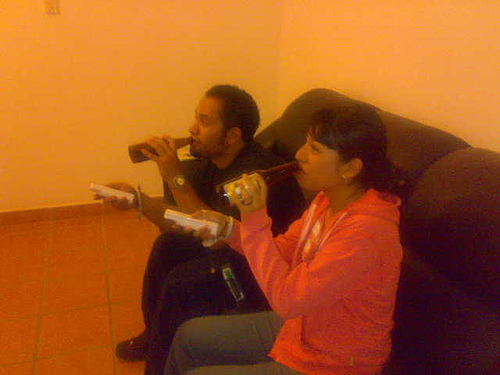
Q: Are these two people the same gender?
A: No, they are both male and female.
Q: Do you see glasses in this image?
A: No, there are no glasses.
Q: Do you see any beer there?
A: Yes, there is beer.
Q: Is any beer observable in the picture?
A: Yes, there is beer.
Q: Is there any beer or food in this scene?
A: Yes, there is beer.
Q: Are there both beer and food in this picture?
A: No, there is beer but no food.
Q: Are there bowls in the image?
A: No, there are no bowls.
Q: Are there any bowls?
A: No, there are no bowls.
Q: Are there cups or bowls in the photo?
A: No, there are no bowls or cups.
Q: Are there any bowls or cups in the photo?
A: No, there are no bowls or cups.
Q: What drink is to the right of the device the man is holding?
A: The drink is beer.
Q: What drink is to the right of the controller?
A: The drink is beer.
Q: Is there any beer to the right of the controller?
A: Yes, there is beer to the right of the controller.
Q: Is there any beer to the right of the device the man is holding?
A: Yes, there is beer to the right of the controller.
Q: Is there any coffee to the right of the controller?
A: No, there is beer to the right of the controller.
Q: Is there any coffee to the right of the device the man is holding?
A: No, there is beer to the right of the controller.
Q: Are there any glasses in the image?
A: No, there are no glasses.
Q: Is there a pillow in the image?
A: No, there are no pillows.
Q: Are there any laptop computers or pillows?
A: No, there are no pillows or laptop computers.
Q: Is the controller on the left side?
A: Yes, the controller is on the left of the image.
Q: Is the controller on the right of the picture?
A: No, the controller is on the left of the image.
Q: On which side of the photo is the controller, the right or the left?
A: The controller is on the left of the image.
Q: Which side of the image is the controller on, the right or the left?
A: The controller is on the left of the image.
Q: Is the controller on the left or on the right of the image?
A: The controller is on the left of the image.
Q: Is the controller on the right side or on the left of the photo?
A: The controller is on the left of the image.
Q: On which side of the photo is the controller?
A: The controller is on the left of the image.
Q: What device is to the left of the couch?
A: The device is a controller.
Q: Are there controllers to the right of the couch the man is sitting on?
A: No, the controller is to the left of the couch.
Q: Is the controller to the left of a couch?
A: Yes, the controller is to the left of a couch.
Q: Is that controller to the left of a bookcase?
A: No, the controller is to the left of a couch.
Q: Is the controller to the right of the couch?
A: No, the controller is to the left of the couch.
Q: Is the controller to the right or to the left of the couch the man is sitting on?
A: The controller is to the left of the couch.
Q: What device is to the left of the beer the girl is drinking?
A: The device is a controller.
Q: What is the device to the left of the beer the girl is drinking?
A: The device is a controller.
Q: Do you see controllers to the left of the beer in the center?
A: Yes, there is a controller to the left of the beer.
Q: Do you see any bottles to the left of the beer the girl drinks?
A: No, there is a controller to the left of the beer.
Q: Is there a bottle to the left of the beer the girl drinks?
A: No, there is a controller to the left of the beer.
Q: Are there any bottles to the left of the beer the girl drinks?
A: No, there is a controller to the left of the beer.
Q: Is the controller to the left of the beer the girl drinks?
A: Yes, the controller is to the left of the beer.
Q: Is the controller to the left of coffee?
A: No, the controller is to the left of the beer.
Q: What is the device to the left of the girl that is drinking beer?
A: The device is a controller.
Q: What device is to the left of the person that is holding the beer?
A: The device is a controller.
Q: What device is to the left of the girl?
A: The device is a controller.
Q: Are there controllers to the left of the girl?
A: Yes, there is a controller to the left of the girl.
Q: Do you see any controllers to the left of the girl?
A: Yes, there is a controller to the left of the girl.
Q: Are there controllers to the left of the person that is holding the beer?
A: Yes, there is a controller to the left of the girl.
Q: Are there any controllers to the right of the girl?
A: No, the controller is to the left of the girl.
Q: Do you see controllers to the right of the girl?
A: No, the controller is to the left of the girl.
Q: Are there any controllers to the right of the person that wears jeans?
A: No, the controller is to the left of the girl.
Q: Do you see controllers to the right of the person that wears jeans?
A: No, the controller is to the left of the girl.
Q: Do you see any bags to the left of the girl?
A: No, there is a controller to the left of the girl.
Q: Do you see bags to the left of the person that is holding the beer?
A: No, there is a controller to the left of the girl.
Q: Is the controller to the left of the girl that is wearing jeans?
A: Yes, the controller is to the left of the girl.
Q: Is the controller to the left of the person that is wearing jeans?
A: Yes, the controller is to the left of the girl.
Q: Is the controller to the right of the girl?
A: No, the controller is to the left of the girl.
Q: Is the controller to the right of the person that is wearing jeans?
A: No, the controller is to the left of the girl.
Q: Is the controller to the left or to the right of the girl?
A: The controller is to the left of the girl.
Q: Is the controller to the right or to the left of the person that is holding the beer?
A: The controller is to the left of the girl.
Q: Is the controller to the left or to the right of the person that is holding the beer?
A: The controller is to the left of the girl.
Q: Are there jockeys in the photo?
A: No, there are no jockeys.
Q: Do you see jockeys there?
A: No, there are no jockeys.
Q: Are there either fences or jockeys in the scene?
A: No, there are no jockeys or fences.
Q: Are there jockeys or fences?
A: No, there are no jockeys or fences.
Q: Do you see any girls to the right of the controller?
A: Yes, there is a girl to the right of the controller.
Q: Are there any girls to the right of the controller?
A: Yes, there is a girl to the right of the controller.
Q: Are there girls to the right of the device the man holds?
A: Yes, there is a girl to the right of the controller.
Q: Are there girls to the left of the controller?
A: No, the girl is to the right of the controller.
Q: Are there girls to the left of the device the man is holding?
A: No, the girl is to the right of the controller.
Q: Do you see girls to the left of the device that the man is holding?
A: No, the girl is to the right of the controller.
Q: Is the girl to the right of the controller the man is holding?
A: Yes, the girl is to the right of the controller.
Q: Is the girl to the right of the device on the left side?
A: Yes, the girl is to the right of the controller.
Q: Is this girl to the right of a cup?
A: No, the girl is to the right of the controller.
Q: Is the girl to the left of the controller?
A: No, the girl is to the right of the controller.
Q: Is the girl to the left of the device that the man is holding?
A: No, the girl is to the right of the controller.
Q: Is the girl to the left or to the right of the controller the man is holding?
A: The girl is to the right of the controller.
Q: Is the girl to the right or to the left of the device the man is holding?
A: The girl is to the right of the controller.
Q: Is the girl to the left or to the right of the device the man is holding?
A: The girl is to the right of the controller.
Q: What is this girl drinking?
A: The girl is drinking beer.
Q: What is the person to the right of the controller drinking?
A: The girl is drinking beer.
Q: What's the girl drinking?
A: The girl is drinking beer.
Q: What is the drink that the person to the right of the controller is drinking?
A: The drink is beer.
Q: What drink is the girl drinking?
A: The girl is drinking beer.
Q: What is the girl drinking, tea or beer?
A: The girl is drinking beer.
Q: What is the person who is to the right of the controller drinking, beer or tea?
A: The girl is drinking beer.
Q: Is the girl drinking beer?
A: Yes, the girl is drinking beer.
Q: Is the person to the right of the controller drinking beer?
A: Yes, the girl is drinking beer.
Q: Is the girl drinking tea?
A: No, the girl is drinking beer.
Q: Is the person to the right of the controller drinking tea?
A: No, the girl is drinking beer.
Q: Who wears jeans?
A: The girl wears jeans.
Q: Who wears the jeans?
A: The girl wears jeans.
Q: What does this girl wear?
A: The girl wears jeans.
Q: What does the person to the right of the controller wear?
A: The girl wears jeans.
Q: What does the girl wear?
A: The girl wears jeans.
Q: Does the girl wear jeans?
A: Yes, the girl wears jeans.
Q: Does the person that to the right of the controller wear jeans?
A: Yes, the girl wears jeans.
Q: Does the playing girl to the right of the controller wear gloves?
A: No, the girl wears jeans.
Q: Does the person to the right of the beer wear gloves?
A: No, the girl wears jeans.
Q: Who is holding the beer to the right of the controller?
A: The girl is holding the beer.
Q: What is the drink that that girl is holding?
A: The drink is beer.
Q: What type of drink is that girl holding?
A: The girl is holding the beer.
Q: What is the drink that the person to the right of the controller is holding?
A: The drink is beer.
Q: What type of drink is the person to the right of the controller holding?
A: The girl is holding the beer.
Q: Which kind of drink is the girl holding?
A: The girl is holding the beer.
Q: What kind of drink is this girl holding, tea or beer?
A: The girl is holding beer.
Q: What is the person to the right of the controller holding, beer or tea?
A: The girl is holding beer.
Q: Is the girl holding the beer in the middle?
A: Yes, the girl is holding the beer.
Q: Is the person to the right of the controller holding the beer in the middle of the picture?
A: Yes, the girl is holding the beer.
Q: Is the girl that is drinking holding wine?
A: No, the girl is holding the beer.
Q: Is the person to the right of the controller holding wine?
A: No, the girl is holding the beer.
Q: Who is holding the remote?
A: The girl is holding the remote.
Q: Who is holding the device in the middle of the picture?
A: The girl is holding the remote.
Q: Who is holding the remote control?
A: The girl is holding the remote.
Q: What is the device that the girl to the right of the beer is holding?
A: The device is a remote control.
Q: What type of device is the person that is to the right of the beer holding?
A: The girl is holding the remote control.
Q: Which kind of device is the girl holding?
A: The girl is holding the remote control.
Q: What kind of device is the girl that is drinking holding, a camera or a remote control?
A: The girl is holding a remote control.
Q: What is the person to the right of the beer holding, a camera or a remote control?
A: The girl is holding a remote control.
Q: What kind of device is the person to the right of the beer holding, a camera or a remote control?
A: The girl is holding a remote control.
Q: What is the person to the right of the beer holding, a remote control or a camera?
A: The girl is holding a remote control.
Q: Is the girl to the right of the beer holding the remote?
A: Yes, the girl is holding the remote.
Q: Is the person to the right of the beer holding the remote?
A: Yes, the girl is holding the remote.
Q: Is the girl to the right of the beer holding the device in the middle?
A: Yes, the girl is holding the remote.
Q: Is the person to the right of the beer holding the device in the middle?
A: Yes, the girl is holding the remote.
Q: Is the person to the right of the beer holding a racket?
A: No, the girl is holding the remote.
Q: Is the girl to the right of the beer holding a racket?
A: No, the girl is holding the remote.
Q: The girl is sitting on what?
A: The girl is sitting on the couch.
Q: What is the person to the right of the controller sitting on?
A: The girl is sitting on the couch.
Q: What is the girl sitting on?
A: The girl is sitting on the couch.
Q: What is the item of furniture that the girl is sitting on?
A: The piece of furniture is a couch.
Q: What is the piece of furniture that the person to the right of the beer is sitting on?
A: The piece of furniture is a couch.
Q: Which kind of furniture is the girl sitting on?
A: The girl is sitting on the couch.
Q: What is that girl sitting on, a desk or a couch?
A: The girl is sitting on a couch.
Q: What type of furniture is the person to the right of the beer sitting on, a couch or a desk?
A: The girl is sitting on a couch.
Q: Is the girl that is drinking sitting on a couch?
A: Yes, the girl is sitting on a couch.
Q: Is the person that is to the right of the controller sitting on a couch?
A: Yes, the girl is sitting on a couch.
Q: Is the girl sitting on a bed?
A: No, the girl is sitting on a couch.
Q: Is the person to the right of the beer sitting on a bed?
A: No, the girl is sitting on a couch.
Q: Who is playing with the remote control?
A: The girl is playing with the remote control.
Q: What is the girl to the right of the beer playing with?
A: The girl is playing with a remote.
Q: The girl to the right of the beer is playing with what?
A: The girl is playing with a remote.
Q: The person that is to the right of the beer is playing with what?
A: The girl is playing with a remote.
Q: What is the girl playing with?
A: The girl is playing with a remote.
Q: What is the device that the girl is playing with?
A: The device is a remote control.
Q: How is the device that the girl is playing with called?
A: The device is a remote control.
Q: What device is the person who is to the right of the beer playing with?
A: The girl is playing with a remote.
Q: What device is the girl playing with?
A: The girl is playing with a remote.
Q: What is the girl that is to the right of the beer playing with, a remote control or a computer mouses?
A: The girl is playing with a remote control.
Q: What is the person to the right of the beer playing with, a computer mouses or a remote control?
A: The girl is playing with a remote control.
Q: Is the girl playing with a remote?
A: Yes, the girl is playing with a remote.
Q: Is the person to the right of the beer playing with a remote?
A: Yes, the girl is playing with a remote.